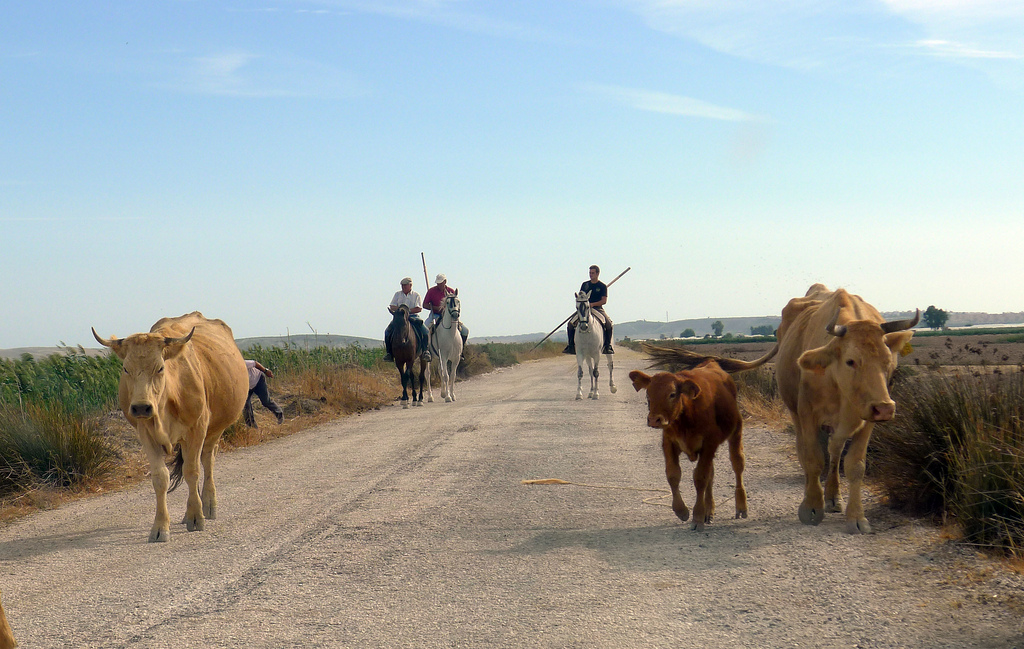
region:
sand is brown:
[407, 554, 494, 613]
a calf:
[625, 364, 756, 549]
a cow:
[780, 279, 911, 529]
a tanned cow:
[102, 304, 273, 543]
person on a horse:
[391, 272, 418, 314]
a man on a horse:
[575, 269, 623, 317]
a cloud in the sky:
[616, 89, 752, 135]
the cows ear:
[787, 340, 829, 378]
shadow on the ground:
[522, 520, 671, 596]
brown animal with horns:
[745, 249, 938, 541]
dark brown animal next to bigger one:
[588, 341, 784, 498]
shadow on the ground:
[465, 477, 647, 643]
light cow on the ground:
[54, 262, 280, 520]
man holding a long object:
[498, 241, 654, 391]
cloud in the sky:
[604, 83, 781, 151]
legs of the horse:
[540, 344, 643, 411]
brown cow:
[84, 304, 259, 526]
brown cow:
[635, 345, 765, 532]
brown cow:
[768, 279, 923, 529]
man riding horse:
[543, 246, 633, 401]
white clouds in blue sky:
[147, 100, 246, 174]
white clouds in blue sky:
[290, 195, 349, 235]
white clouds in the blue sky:
[438, 95, 555, 150]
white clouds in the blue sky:
[680, 99, 734, 132]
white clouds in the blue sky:
[665, 191, 729, 255]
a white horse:
[564, 283, 625, 405]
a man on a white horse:
[555, 256, 622, 403]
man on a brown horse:
[379, 272, 431, 408]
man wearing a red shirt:
[417, 269, 462, 323]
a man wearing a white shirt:
[379, 267, 430, 334]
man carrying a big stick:
[526, 251, 640, 357]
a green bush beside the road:
[913, 367, 1021, 567]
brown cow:
[76, 288, 276, 524]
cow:
[610, 339, 766, 516]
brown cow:
[755, 259, 930, 493]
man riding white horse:
[544, 241, 624, 375]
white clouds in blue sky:
[236, 157, 310, 247]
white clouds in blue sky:
[639, 117, 712, 169]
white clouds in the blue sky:
[899, 52, 983, 114]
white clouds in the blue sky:
[732, 74, 812, 172]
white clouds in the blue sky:
[846, 198, 952, 296]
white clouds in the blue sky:
[227, 88, 281, 156]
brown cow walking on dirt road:
[84, 291, 277, 561]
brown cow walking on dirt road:
[618, 332, 783, 542]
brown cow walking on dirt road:
[765, 252, 918, 516]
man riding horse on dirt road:
[547, 252, 625, 388]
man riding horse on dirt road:
[408, 263, 506, 399]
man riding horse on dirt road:
[364, 251, 428, 407]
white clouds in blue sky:
[152, 76, 226, 144]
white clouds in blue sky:
[394, 29, 496, 127]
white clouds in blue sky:
[649, 86, 766, 157]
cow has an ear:
[802, 331, 841, 371]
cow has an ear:
[887, 322, 913, 354]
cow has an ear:
[628, 363, 652, 392]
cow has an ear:
[167, 324, 199, 362]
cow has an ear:
[88, 327, 114, 357]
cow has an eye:
[671, 384, 681, 397]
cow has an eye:
[159, 362, 169, 375]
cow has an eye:
[119, 362, 127, 375]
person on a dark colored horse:
[386, 272, 428, 356]